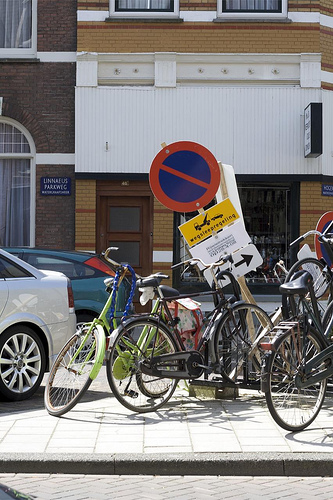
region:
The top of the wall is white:
[103, 91, 261, 134]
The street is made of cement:
[63, 421, 254, 498]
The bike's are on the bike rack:
[42, 239, 331, 427]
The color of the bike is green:
[76, 292, 169, 394]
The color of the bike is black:
[114, 282, 246, 383]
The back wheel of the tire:
[106, 312, 186, 416]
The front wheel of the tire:
[211, 294, 278, 389]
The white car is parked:
[0, 236, 80, 419]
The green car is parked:
[12, 238, 129, 338]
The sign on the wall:
[35, 171, 74, 199]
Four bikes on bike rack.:
[22, 213, 331, 455]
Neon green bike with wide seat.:
[33, 232, 199, 426]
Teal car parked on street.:
[1, 234, 126, 361]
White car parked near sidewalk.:
[0, 232, 135, 457]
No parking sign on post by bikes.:
[146, 125, 262, 308]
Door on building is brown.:
[83, 164, 167, 303]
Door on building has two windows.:
[91, 173, 172, 291]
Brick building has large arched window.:
[0, 101, 48, 258]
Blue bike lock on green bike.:
[69, 246, 170, 345]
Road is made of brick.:
[2, 449, 318, 498]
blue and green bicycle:
[36, 239, 184, 424]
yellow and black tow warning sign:
[173, 195, 242, 246]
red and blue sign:
[145, 140, 222, 213]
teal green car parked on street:
[0, 240, 135, 358]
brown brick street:
[0, 476, 331, 498]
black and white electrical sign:
[304, 100, 323, 159]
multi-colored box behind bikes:
[160, 295, 204, 353]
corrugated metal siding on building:
[73, 81, 332, 174]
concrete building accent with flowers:
[79, 51, 323, 86]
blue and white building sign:
[38, 175, 72, 196]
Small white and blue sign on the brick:
[39, 176, 72, 199]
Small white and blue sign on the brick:
[318, 183, 331, 197]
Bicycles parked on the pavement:
[50, 248, 321, 424]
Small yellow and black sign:
[165, 214, 252, 239]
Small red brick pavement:
[14, 471, 49, 498]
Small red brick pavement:
[55, 472, 84, 498]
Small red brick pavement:
[93, 472, 145, 494]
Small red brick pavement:
[137, 474, 164, 499]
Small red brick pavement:
[165, 474, 200, 498]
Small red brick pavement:
[191, 474, 251, 498]